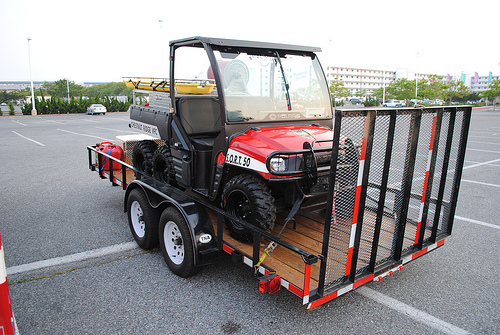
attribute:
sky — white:
[60, 23, 92, 52]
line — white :
[10, 129, 45, 149]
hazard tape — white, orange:
[94, 166, 128, 188]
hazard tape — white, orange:
[222, 245, 300, 299]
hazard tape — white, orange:
[302, 263, 310, 304]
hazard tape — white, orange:
[344, 117, 369, 275]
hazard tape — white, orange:
[414, 112, 438, 244]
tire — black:
[219, 176, 276, 242]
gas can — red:
[88, 138, 127, 180]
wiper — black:
[270, 48, 295, 110]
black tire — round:
[218, 172, 278, 244]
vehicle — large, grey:
[86, 100, 110, 118]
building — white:
[322, 64, 394, 101]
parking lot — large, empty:
[5, 79, 498, 329]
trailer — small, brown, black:
[77, 94, 477, 316]